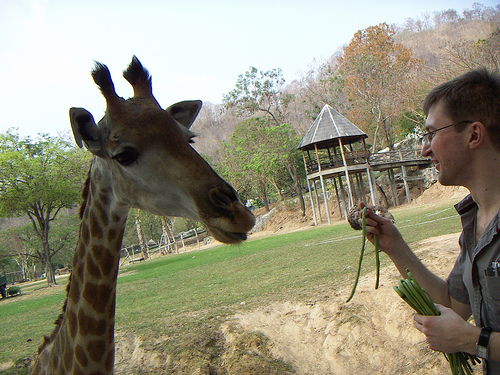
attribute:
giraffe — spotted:
[28, 42, 286, 374]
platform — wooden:
[301, 101, 398, 231]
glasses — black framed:
[420, 120, 479, 142]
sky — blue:
[7, 0, 482, 146]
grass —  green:
[2, 203, 467, 373]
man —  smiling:
[360, 65, 497, 373]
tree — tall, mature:
[3, 125, 112, 290]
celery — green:
[345, 205, 380, 304]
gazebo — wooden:
[298, 102, 379, 224]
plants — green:
[333, 194, 390, 299]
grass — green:
[0, 196, 499, 373]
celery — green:
[387, 264, 482, 374]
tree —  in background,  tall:
[4, 137, 85, 213]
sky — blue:
[1, 1, 497, 196]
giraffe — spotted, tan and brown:
[7, 47, 268, 367]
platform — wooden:
[292, 96, 384, 236]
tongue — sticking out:
[218, 228, 245, 242]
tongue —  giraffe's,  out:
[223, 229, 250, 239]